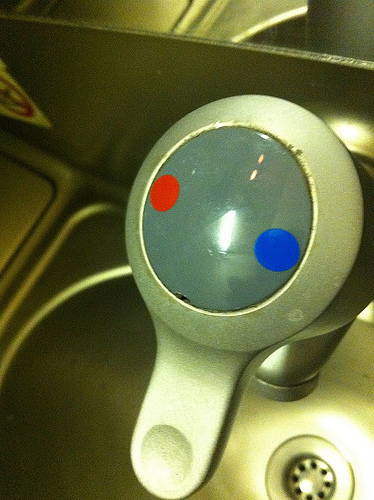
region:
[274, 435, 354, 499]
metal sink drain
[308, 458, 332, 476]
holes in sink drain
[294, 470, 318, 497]
light reflected on sink drain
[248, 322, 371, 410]
metal faucet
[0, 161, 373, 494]
metal sink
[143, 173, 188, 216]
red circle on faucet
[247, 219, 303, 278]
blue circle on faucet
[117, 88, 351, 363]
round top of metal faucet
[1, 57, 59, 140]
red and white sign sink backsplash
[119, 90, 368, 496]
silver paddle with blue and red dots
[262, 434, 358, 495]
round silver sink drain with holes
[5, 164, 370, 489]
right square side of silver sink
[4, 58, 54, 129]
white sign with red warning circle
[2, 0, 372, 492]
right side of industrial stainless steel sink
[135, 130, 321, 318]
grey circular inset on faucet lever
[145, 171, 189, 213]
red faucet button for hot water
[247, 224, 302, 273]
blue button for cold water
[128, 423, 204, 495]
thumb impression in faucet lever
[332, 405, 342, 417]
part of a sink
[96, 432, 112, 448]
edge of a sink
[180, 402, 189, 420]
edge of a sink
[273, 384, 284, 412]
part of a pipe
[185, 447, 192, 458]
edge of a sink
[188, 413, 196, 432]
edge of a sink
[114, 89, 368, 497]
an extreme closeup of a sink faucet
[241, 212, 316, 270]
the blue indicates cold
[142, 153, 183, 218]
the red indicates hot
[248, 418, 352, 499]
the drain has 7 holes in it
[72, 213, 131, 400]
a stainless steel sink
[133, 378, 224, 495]
light reflecting off the handle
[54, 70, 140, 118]
the back splash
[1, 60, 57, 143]
a red & white sign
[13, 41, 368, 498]
a truly odd photo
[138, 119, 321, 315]
the top center of the faucet